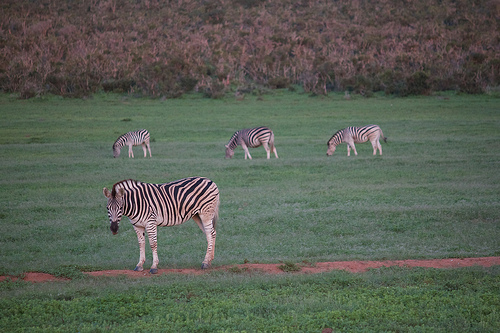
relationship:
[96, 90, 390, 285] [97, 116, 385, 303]
group of zebras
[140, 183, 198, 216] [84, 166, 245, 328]
stripes on zebra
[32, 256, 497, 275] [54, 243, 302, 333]
trail in field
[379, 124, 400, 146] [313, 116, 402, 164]
tail of zebra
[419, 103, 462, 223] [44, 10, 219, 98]
field of bushes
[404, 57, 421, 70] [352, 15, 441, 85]
leaves on tree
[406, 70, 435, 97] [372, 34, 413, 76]
leaves on tree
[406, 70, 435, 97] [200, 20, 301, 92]
leaves on tree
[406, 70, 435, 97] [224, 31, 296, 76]
leaves on tree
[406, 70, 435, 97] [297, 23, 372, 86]
leaves on trees